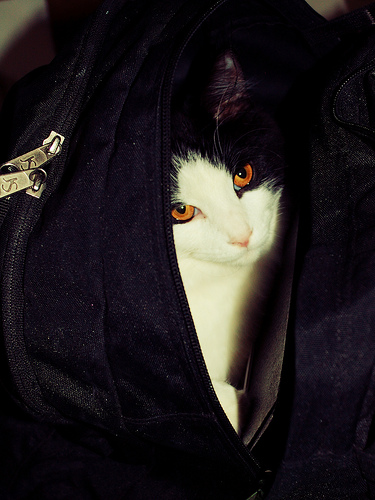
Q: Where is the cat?
A: In the bag.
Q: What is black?
A: Bag.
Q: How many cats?
A: One.